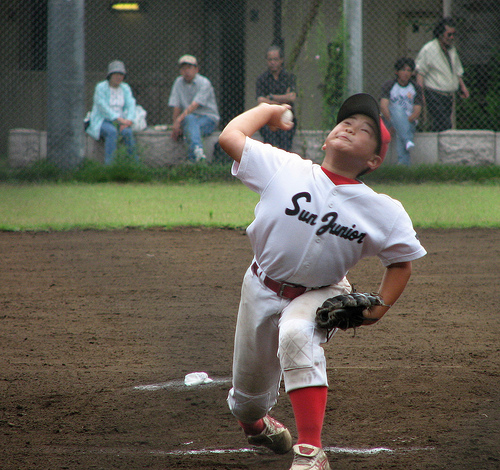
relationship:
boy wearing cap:
[219, 92, 427, 469] [336, 93, 391, 172]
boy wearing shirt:
[219, 92, 427, 469] [231, 136, 427, 289]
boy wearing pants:
[219, 92, 427, 469] [227, 259, 353, 422]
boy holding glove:
[219, 92, 427, 469] [316, 289, 386, 342]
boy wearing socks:
[219, 92, 427, 469] [235, 381, 328, 452]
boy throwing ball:
[219, 92, 427, 469] [279, 106, 294, 125]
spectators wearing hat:
[84, 59, 140, 164] [105, 57, 125, 80]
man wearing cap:
[167, 52, 221, 161] [177, 53, 197, 70]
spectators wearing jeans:
[84, 59, 140, 164] [100, 120, 137, 168]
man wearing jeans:
[167, 52, 221, 161] [182, 109, 215, 160]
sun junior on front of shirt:
[283, 189, 367, 244] [231, 136, 427, 289]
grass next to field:
[0, 175, 499, 233] [1, 224, 499, 470]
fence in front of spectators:
[0, 0, 498, 186] [84, 41, 423, 164]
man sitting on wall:
[167, 52, 221, 161] [13, 128, 499, 167]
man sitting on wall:
[255, 45, 301, 154] [13, 128, 499, 167]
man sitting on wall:
[379, 53, 423, 168] [13, 128, 499, 167]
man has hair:
[411, 14, 468, 131] [432, 17, 456, 41]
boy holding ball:
[219, 92, 427, 469] [279, 106, 294, 125]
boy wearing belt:
[219, 92, 427, 469] [250, 259, 331, 301]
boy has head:
[219, 92, 427, 469] [318, 90, 391, 176]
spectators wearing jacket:
[84, 59, 140, 164] [86, 79, 136, 140]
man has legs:
[167, 52, 221, 161] [178, 107, 217, 165]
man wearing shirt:
[255, 45, 301, 154] [255, 67, 296, 112]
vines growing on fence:
[296, 2, 350, 137] [0, 0, 498, 186]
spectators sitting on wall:
[84, 59, 140, 164] [13, 128, 499, 167]